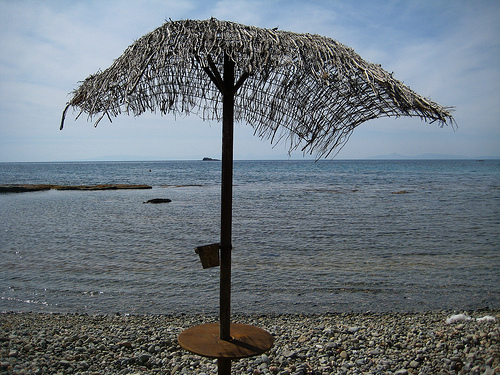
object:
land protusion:
[0, 183, 152, 195]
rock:
[0, 317, 500, 375]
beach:
[0, 309, 499, 375]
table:
[177, 322, 275, 359]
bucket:
[194, 242, 220, 269]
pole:
[218, 55, 236, 341]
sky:
[387, 10, 484, 71]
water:
[3, 202, 187, 311]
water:
[302, 201, 457, 284]